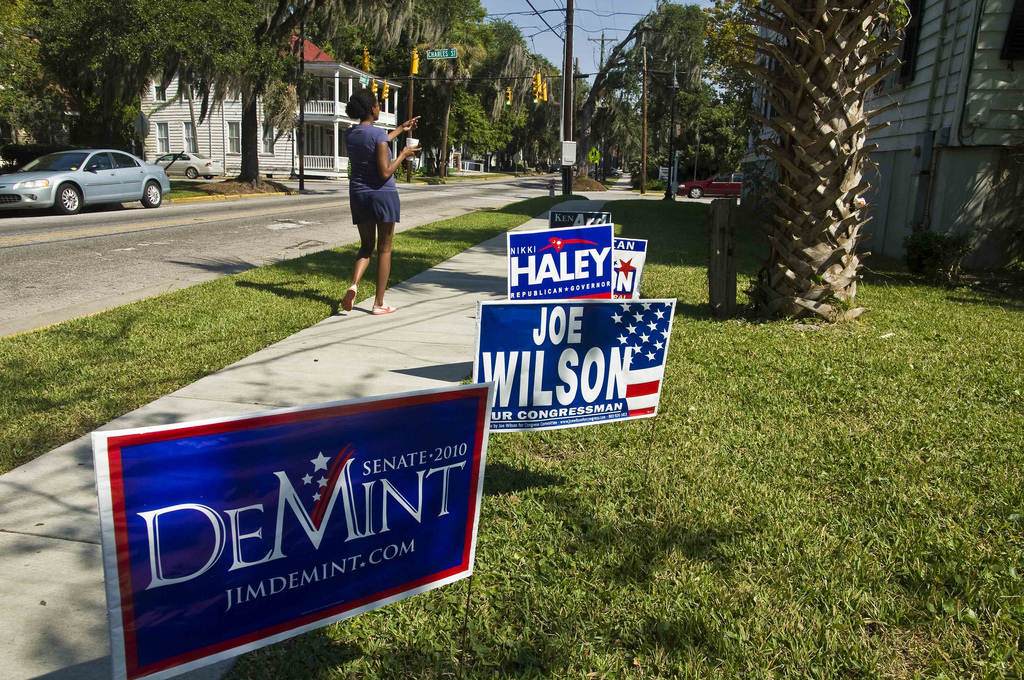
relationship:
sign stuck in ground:
[598, 235, 653, 297] [7, 193, 1014, 669]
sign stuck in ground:
[499, 218, 620, 307] [7, 193, 1014, 669]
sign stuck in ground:
[474, 281, 675, 433] [7, 193, 1014, 669]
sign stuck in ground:
[87, 377, 490, 672] [7, 193, 1014, 669]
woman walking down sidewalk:
[340, 91, 423, 315] [4, 177, 625, 677]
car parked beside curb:
[2, 145, 174, 216] [0, 174, 298, 210]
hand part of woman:
[398, 142, 428, 158] [340, 91, 423, 315]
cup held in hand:
[396, 131, 419, 154] [398, 142, 428, 158]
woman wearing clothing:
[346, 122, 397, 221] [344, 126, 405, 228]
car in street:
[2, 145, 174, 216] [5, 138, 162, 212]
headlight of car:
[2, 165, 41, 182] [1, 136, 172, 217]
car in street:
[1, 136, 172, 217] [1, 173, 565, 344]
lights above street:
[332, 45, 560, 123] [1, 157, 580, 326]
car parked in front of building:
[159, 143, 217, 169] [137, 21, 401, 190]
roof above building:
[282, 39, 352, 62] [137, 21, 402, 178]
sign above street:
[408, 40, 462, 59] [1, 173, 565, 344]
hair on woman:
[340, 89, 376, 118] [340, 91, 423, 315]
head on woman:
[337, 94, 391, 136] [340, 91, 423, 315]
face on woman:
[368, 105, 387, 124] [340, 91, 423, 315]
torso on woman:
[340, 118, 379, 182] [336, 84, 443, 327]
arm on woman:
[371, 144, 430, 179] [336, 84, 443, 327]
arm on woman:
[364, 106, 415, 145] [340, 91, 423, 315]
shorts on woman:
[349, 191, 402, 225] [331, 80, 437, 316]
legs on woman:
[336, 214, 395, 303] [336, 84, 443, 327]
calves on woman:
[336, 245, 406, 296] [331, 80, 437, 316]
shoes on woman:
[332, 282, 406, 327] [340, 91, 423, 315]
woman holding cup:
[340, 91, 423, 315] [407, 129, 425, 156]